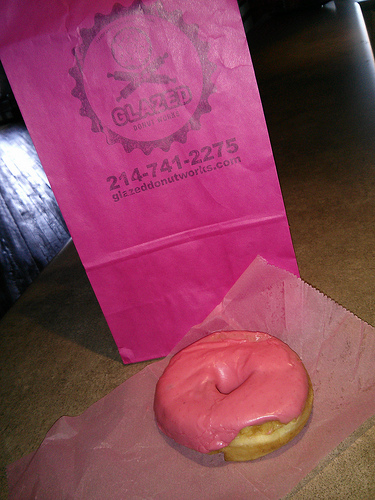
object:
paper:
[13, 244, 372, 499]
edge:
[252, 252, 374, 331]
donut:
[151, 319, 318, 471]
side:
[222, 407, 317, 466]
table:
[1, 0, 375, 500]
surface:
[0, 241, 162, 500]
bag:
[3, 2, 315, 369]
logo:
[66, 5, 219, 161]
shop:
[66, 7, 254, 210]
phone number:
[102, 134, 247, 196]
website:
[97, 150, 246, 208]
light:
[0, 121, 70, 276]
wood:
[0, 116, 69, 312]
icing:
[218, 376, 315, 462]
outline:
[140, 385, 313, 475]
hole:
[206, 357, 260, 400]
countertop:
[0, 0, 373, 500]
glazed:
[106, 80, 197, 131]